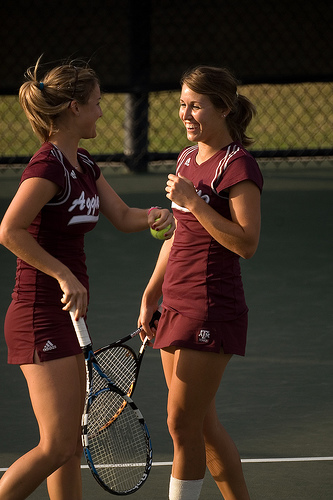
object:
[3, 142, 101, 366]
outfit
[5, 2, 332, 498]
tennis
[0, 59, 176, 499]
woman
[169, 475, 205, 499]
sock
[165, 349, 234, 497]
legs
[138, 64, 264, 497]
player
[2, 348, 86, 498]
legs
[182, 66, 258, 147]
brown hair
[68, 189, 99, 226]
print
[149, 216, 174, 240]
ball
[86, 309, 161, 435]
racquet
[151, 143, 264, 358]
marroon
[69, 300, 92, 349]
handle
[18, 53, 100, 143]
blond hair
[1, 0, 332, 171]
fence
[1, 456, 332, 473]
line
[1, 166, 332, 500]
court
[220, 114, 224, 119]
earring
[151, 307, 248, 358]
skirt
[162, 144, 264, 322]
top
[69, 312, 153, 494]
racquet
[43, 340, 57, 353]
logo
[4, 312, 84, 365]
skirt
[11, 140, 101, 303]
jersey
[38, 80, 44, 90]
hairband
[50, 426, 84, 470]
knees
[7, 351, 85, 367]
hem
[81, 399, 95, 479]
edge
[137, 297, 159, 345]
hand